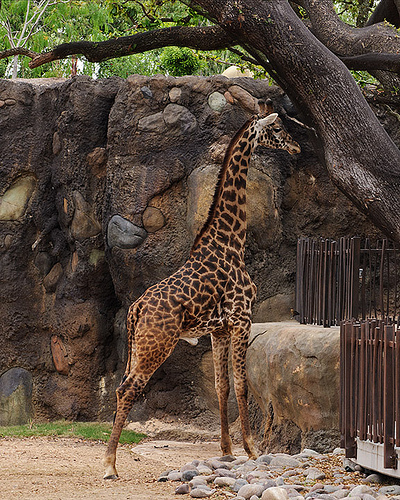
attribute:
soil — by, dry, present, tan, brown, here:
[31, 437, 108, 491]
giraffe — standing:
[135, 108, 332, 423]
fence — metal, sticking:
[295, 236, 379, 331]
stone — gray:
[262, 309, 375, 456]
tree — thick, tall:
[244, 10, 373, 157]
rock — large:
[87, 191, 193, 300]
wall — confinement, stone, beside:
[53, 83, 227, 353]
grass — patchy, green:
[24, 386, 112, 434]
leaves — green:
[71, 8, 187, 62]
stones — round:
[223, 436, 328, 497]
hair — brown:
[212, 139, 234, 213]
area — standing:
[101, 56, 273, 78]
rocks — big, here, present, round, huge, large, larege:
[27, 103, 167, 266]